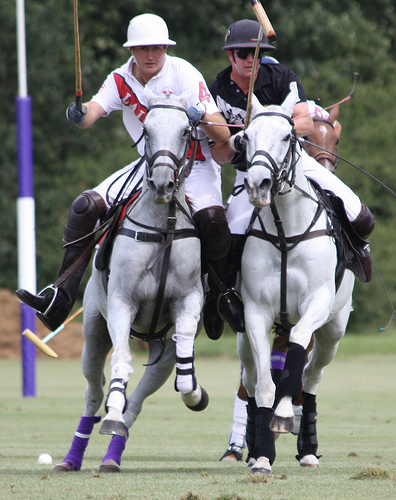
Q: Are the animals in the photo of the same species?
A: Yes, all the animals are horses.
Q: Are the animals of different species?
A: No, all the animals are horses.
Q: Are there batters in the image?
A: No, there are no batters.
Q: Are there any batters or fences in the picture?
A: No, there are no batters or fences.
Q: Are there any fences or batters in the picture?
A: No, there are no batters or fences.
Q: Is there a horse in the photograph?
A: Yes, there is a horse.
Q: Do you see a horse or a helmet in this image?
A: Yes, there is a horse.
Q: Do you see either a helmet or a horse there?
A: Yes, there is a horse.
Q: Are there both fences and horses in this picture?
A: No, there is a horse but no fences.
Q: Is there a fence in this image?
A: No, there are no fences.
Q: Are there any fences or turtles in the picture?
A: No, there are no fences or turtles.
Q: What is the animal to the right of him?
A: The animal is a horse.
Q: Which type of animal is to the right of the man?
A: The animal is a horse.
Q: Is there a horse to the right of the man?
A: Yes, there is a horse to the right of the man.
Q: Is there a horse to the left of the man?
A: No, the horse is to the right of the man.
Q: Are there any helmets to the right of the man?
A: No, there is a horse to the right of the man.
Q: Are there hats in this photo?
A: Yes, there is a hat.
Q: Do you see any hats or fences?
A: Yes, there is a hat.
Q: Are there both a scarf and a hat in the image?
A: No, there is a hat but no scarves.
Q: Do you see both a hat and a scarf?
A: No, there is a hat but no scarves.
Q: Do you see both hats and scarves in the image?
A: No, there is a hat but no scarves.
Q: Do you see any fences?
A: No, there are no fences.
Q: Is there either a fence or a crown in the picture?
A: No, there are no fences or crowns.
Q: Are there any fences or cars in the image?
A: No, there are no fences or cars.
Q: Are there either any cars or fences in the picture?
A: No, there are no fences or cars.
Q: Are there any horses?
A: Yes, there is a horse.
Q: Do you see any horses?
A: Yes, there is a horse.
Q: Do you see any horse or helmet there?
A: Yes, there is a horse.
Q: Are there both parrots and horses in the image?
A: No, there is a horse but no parrots.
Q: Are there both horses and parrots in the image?
A: No, there is a horse but no parrots.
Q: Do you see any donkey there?
A: No, there are no donkeys.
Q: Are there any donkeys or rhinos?
A: No, there are no donkeys or rhinos.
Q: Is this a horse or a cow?
A: This is a horse.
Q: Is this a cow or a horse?
A: This is a horse.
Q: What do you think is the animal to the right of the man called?
A: The animal is a horse.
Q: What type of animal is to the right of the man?
A: The animal is a horse.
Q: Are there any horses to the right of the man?
A: Yes, there is a horse to the right of the man.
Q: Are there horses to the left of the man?
A: No, the horse is to the right of the man.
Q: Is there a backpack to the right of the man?
A: No, there is a horse to the right of the man.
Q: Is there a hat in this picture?
A: Yes, there is a hat.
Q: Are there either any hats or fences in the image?
A: Yes, there is a hat.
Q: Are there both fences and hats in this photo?
A: No, there is a hat but no fences.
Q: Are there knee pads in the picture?
A: No, there are no knee pads.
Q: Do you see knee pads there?
A: No, there are no knee pads.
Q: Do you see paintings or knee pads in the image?
A: No, there are no knee pads or paintings.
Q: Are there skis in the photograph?
A: No, there are no skis.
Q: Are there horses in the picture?
A: Yes, there is a horse.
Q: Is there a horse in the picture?
A: Yes, there is a horse.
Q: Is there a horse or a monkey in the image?
A: Yes, there is a horse.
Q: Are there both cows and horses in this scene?
A: No, there is a horse but no cows.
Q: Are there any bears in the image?
A: No, there are no bears.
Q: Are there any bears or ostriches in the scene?
A: No, there are no bears or ostriches.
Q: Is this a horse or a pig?
A: This is a horse.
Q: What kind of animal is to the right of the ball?
A: The animal is a horse.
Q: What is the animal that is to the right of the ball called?
A: The animal is a horse.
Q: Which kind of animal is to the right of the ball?
A: The animal is a horse.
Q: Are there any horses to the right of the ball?
A: Yes, there is a horse to the right of the ball.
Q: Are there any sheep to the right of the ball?
A: No, there is a horse to the right of the ball.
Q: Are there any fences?
A: No, there are no fences.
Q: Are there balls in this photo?
A: Yes, there is a ball.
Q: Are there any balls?
A: Yes, there is a ball.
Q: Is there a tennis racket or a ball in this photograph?
A: Yes, there is a ball.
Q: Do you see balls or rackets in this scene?
A: Yes, there is a ball.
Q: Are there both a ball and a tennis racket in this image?
A: No, there is a ball but no rackets.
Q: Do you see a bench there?
A: No, there are no benches.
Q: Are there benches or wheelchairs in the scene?
A: No, there are no benches or wheelchairs.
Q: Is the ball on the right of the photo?
A: No, the ball is on the left of the image.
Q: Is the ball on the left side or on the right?
A: The ball is on the left of the image.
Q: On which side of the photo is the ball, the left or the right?
A: The ball is on the left of the image.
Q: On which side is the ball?
A: The ball is on the left of the image.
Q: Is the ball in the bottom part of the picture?
A: Yes, the ball is in the bottom of the image.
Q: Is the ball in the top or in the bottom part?
A: The ball is in the bottom of the image.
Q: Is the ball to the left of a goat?
A: No, the ball is to the left of a horse.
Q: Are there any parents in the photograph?
A: No, there are no parents.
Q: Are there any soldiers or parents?
A: No, there are no parents or soldiers.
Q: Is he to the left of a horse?
A: Yes, the man is to the left of a horse.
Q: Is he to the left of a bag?
A: No, the man is to the left of a horse.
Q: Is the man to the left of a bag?
A: No, the man is to the left of the horse.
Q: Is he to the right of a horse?
A: No, the man is to the left of a horse.